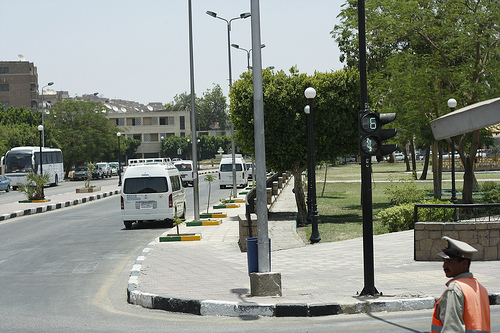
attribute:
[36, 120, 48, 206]
street lamp — white, black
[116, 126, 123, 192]
street lamp — white, black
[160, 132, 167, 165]
street lamp — white, black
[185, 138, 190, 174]
street lamp — white, black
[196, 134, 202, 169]
street lamp — white, black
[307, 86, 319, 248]
street lamp — white, black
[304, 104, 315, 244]
street lamp — white, black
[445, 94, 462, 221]
street lamp — white, black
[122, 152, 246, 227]
vans — white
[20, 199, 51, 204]
planters — yellow, green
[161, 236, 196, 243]
planters — yellow, green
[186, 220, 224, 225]
planters — yellow, green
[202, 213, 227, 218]
planters — yellow, green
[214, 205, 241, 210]
planters — yellow, green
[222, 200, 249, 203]
planters — yellow, green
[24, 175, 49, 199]
trees — small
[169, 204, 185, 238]
trees — small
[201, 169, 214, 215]
trees — small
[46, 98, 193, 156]
office building — beige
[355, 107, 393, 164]
crosswalk light — black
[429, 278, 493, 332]
vest — orange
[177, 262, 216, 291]
bricks — beige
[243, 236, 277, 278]
trash bin — blue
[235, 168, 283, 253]
fence — metal, stone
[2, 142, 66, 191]
bus — white, public service, public transit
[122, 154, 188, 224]
van — white, large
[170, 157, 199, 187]
van — white, large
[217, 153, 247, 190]
van — white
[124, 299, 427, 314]
street curb — striped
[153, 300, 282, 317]
stripes — black, white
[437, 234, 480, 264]
hat — tan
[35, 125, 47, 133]
globe lights — white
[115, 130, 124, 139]
globe lights — white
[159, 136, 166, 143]
globe lights — white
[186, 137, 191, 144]
globe lights — white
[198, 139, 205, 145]
globe lights — white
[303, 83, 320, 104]
globe lights — white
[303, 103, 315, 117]
globe lights — white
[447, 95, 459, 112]
globe lights — white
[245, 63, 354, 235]
sapling tree — young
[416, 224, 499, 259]
wall — stone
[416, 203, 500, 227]
rail — metal